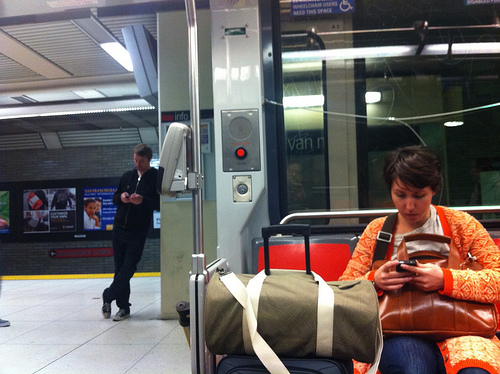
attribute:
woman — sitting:
[336, 143, 498, 374]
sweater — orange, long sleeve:
[336, 204, 498, 372]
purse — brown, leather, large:
[373, 232, 497, 338]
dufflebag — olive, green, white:
[204, 268, 386, 373]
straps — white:
[217, 265, 385, 374]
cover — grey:
[220, 106, 261, 174]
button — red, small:
[236, 148, 244, 157]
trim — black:
[234, 146, 247, 160]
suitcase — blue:
[214, 351, 350, 373]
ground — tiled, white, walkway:
[1, 275, 191, 373]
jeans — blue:
[377, 335, 489, 373]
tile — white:
[34, 344, 154, 373]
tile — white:
[5, 318, 116, 345]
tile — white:
[87, 317, 178, 344]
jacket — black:
[112, 167, 161, 230]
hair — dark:
[384, 143, 441, 194]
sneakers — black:
[99, 296, 132, 324]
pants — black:
[102, 223, 147, 309]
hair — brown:
[134, 142, 153, 164]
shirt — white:
[390, 203, 450, 260]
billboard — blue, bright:
[81, 186, 123, 231]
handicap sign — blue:
[290, 0, 357, 19]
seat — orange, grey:
[250, 233, 357, 287]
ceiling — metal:
[0, 0, 208, 107]